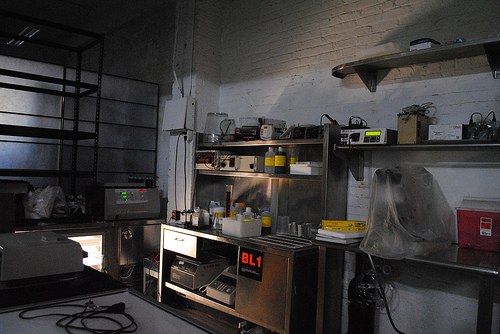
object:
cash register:
[203, 262, 240, 305]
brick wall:
[158, 0, 500, 334]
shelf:
[329, 136, 498, 153]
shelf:
[258, 132, 318, 147]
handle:
[173, 237, 186, 242]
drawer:
[155, 217, 204, 262]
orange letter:
[248, 252, 257, 267]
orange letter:
[255, 255, 264, 268]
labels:
[272, 154, 287, 167]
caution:
[478, 216, 493, 237]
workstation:
[147, 104, 348, 334]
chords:
[173, 133, 183, 211]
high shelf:
[331, 35, 500, 94]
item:
[406, 37, 442, 51]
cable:
[19, 297, 139, 332]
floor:
[0, 282, 241, 333]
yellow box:
[321, 218, 366, 234]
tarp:
[356, 159, 459, 263]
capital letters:
[241, 251, 249, 264]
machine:
[99, 183, 163, 221]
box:
[454, 195, 500, 255]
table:
[310, 239, 500, 334]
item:
[221, 217, 263, 238]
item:
[199, 208, 210, 228]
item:
[210, 205, 224, 234]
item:
[260, 207, 273, 236]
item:
[230, 201, 244, 216]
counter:
[151, 209, 321, 333]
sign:
[241, 251, 263, 268]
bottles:
[273, 146, 287, 175]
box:
[288, 160, 325, 176]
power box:
[159, 93, 199, 131]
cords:
[183, 132, 189, 214]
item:
[365, 163, 435, 260]